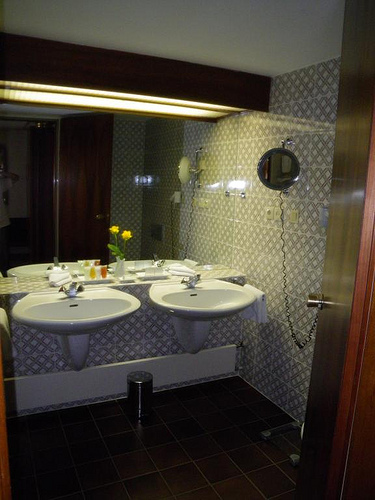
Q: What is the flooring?
A: Tile.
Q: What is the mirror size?
A: Larg.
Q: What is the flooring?
A: Tile.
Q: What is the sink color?
A: White.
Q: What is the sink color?
A: White.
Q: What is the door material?
A: Wooden.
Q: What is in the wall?
A: Mirror.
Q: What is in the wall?
A: Mirror.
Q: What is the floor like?
A: Tiled.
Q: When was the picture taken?
A: Daytime.